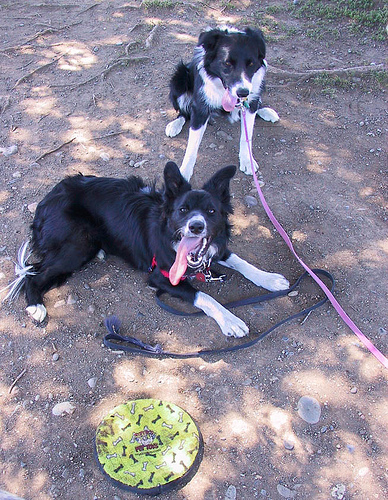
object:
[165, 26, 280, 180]
dog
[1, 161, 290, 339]
dog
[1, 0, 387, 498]
dirt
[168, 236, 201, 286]
tongue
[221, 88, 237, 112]
tongue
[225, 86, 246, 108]
mouth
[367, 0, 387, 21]
grass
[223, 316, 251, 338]
paw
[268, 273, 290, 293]
paw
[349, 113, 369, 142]
ground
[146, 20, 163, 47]
tree roots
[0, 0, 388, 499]
ground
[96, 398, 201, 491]
dog toy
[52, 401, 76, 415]
rock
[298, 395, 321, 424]
rock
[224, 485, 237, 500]
rock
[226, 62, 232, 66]
brown eye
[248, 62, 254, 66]
brown eye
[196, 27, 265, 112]
head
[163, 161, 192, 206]
ears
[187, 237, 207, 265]
teeth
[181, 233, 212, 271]
mouth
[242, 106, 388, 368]
leash